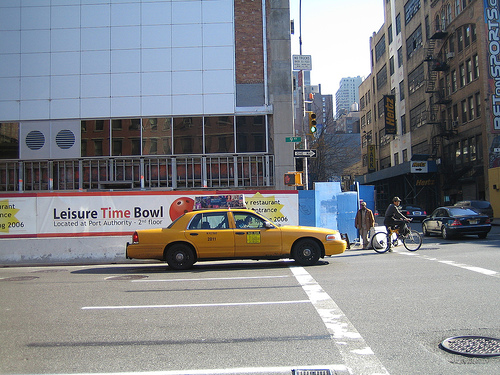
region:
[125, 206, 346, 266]
a yellow taxi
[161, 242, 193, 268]
rear wheel of a car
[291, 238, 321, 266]
front wheel of a car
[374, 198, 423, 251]
a man on a bike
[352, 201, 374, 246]
a man standing on the street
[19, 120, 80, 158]
circular metal grates on metal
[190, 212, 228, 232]
rear cab window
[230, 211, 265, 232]
front cab window and cab driver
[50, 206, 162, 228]
red and black lettering on white panel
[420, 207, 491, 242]
a blue luxury car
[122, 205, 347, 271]
Yellow taxicab on the street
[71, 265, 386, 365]
White lines painted on the road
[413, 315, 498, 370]
Man hole cover in the street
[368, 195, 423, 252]
Man on a bicycle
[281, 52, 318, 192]
Vertical street post with multiple signs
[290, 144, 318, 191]
One-way street sign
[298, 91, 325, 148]
Traffic signal light with green lit up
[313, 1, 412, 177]
Several buildings of different height and design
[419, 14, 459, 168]
Black fire escape stairs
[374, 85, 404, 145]
Hertz outdoor hanging advertisement banner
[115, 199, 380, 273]
a yellow taxicab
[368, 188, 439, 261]
a man on a bicycle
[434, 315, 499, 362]
a man hole cover on a city street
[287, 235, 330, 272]
the front wheel of a yellow taxicap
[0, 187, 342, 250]
an advertisement sign on a city street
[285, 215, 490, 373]
a crosswalk on a city street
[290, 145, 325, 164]
a one way street sign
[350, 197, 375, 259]
a man walking on the street wearing a brown jacket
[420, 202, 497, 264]
a car driving down a city street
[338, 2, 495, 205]
the facade of buildings on a city street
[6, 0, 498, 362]
A city street scene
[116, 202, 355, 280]
A taxi cab is on the street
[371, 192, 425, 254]
A man riding a bicycle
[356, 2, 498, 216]
Buildings are beside the street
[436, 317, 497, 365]
A manhole cover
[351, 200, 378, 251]
A man is standing on the corner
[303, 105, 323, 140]
The traffic light is green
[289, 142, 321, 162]
A street sign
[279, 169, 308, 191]
A crosswalk signal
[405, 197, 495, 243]
Cars are travelling down the street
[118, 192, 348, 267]
A yellow taxi car.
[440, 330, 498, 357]
A manhole on the road.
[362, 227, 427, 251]
A bicycle.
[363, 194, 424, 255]
A man on a bicycle.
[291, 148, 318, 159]
A black and white "One Way" sign.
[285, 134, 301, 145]
A green and white street sign.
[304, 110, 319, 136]
A traffic light on green.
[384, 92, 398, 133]
A black and yellow Hertz banner hanging from a building.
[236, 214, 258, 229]
A taxi driver in the front seat of a taxi car.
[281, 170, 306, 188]
A crosswalk sign indicating not to walk.